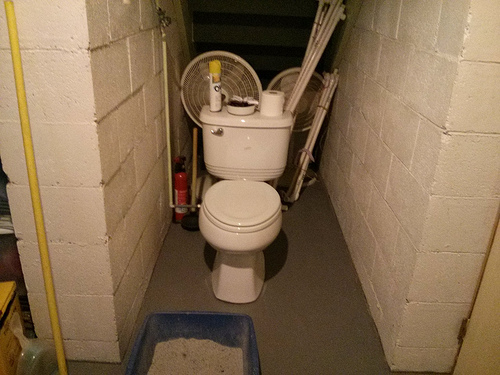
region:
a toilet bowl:
[197, 106, 294, 306]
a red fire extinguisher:
[172, 156, 188, 220]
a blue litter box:
[129, 307, 261, 373]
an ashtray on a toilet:
[224, 95, 256, 112]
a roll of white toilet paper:
[260, 87, 286, 118]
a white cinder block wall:
[317, 2, 497, 369]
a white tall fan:
[175, 50, 261, 126]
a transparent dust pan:
[6, 310, 59, 373]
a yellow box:
[0, 275, 25, 372]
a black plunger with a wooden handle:
[177, 126, 200, 234]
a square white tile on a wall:
[77, 0, 115, 46]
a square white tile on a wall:
[83, 50, 141, 115]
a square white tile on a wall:
[85, 98, 151, 179]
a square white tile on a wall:
[96, 153, 148, 226]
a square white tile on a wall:
[424, 12, 498, 61]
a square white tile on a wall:
[434, 50, 499, 131]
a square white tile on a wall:
[394, 117, 458, 179]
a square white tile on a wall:
[432, 187, 496, 262]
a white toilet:
[194, 75, 310, 296]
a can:
[200, 50, 249, 125]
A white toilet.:
[196, 102, 295, 306]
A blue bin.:
[121, 302, 266, 373]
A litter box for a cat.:
[121, 307, 259, 373]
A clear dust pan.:
[9, 312, 57, 373]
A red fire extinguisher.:
[169, 155, 189, 224]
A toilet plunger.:
[184, 132, 200, 233]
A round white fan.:
[180, 55, 262, 130]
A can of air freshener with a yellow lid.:
[207, 61, 222, 112]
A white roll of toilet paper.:
[259, 90, 284, 113]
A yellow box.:
[1, 282, 26, 374]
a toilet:
[196, 103, 297, 304]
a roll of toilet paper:
[258, 88, 285, 117]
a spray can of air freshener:
[207, 58, 224, 113]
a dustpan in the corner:
[8, 312, 60, 374]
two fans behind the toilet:
[176, 46, 327, 135]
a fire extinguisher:
[168, 151, 193, 226]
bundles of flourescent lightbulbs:
[283, 0, 350, 207]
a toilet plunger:
[177, 124, 200, 234]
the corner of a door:
[448, 203, 498, 373]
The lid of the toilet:
[203, 178, 280, 230]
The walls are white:
[360, 151, 423, 239]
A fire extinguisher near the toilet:
[171, 157, 188, 222]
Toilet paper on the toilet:
[261, 88, 283, 117]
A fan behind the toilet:
[226, 62, 250, 97]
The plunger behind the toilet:
[190, 128, 197, 233]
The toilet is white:
[228, 186, 247, 214]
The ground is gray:
[295, 243, 337, 337]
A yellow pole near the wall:
[26, 186, 68, 370]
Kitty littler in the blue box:
[154, 339, 237, 374]